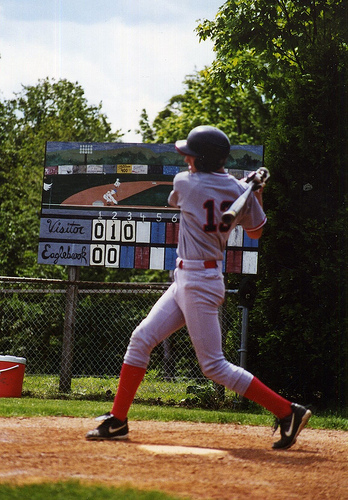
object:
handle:
[252, 167, 268, 183]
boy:
[85, 125, 312, 452]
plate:
[0, 355, 26, 399]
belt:
[176, 257, 222, 272]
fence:
[0, 276, 256, 413]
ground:
[0, 415, 348, 499]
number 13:
[203, 199, 235, 233]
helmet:
[175, 118, 230, 175]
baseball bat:
[221, 171, 264, 225]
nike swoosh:
[285, 413, 295, 436]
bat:
[221, 170, 265, 225]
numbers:
[90, 220, 136, 268]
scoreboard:
[38, 143, 266, 274]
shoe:
[271, 402, 311, 451]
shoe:
[85, 411, 130, 442]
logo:
[285, 413, 295, 436]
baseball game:
[103, 128, 316, 447]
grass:
[74, 376, 109, 408]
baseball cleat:
[270, 402, 311, 449]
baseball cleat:
[85, 415, 128, 439]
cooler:
[0, 355, 25, 397]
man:
[85, 124, 312, 448]